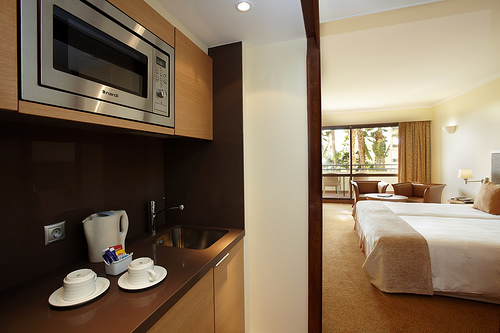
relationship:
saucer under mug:
[47, 275, 111, 307] [62, 266, 99, 302]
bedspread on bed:
[388, 201, 498, 298] [339, 184, 498, 314]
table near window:
[366, 184, 407, 204] [323, 123, 403, 198]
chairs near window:
[346, 177, 366, 201] [323, 123, 403, 198]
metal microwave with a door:
[19, 2, 177, 130] [38, 6, 151, 111]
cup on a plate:
[128, 256, 154, 284] [116, 263, 167, 290]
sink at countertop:
[150, 225, 231, 250] [144, 217, 248, 274]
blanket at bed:
[356, 198, 494, 290] [353, 198, 496, 283]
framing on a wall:
[297, 20, 334, 331] [252, 33, 339, 331]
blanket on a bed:
[356, 198, 494, 290] [354, 214, 499, 303]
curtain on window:
[394, 120, 431, 177] [326, 125, 398, 177]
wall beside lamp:
[414, 122, 499, 218] [415, 147, 484, 204]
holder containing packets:
[101, 244, 133, 276] [101, 244, 126, 259]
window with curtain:
[319, 113, 417, 215] [396, 120, 430, 186]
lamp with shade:
[455, 165, 490, 188] [432, 154, 474, 204]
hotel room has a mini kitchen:
[5, 2, 497, 331] [20, 8, 276, 330]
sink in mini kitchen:
[145, 189, 232, 266] [14, 23, 306, 331]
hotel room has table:
[5, 2, 497, 331] [360, 189, 408, 202]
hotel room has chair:
[5, 2, 497, 331] [346, 174, 381, 199]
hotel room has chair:
[5, 2, 497, 331] [392, 171, 439, 201]